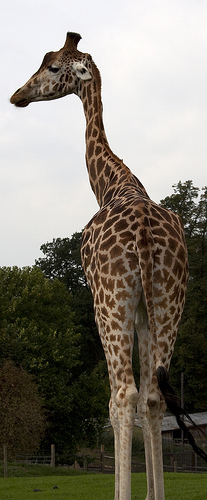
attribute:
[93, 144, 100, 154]
spot — brown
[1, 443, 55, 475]
poles — wooden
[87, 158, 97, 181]
spot — brown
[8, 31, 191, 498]
giraffe — tall, yellow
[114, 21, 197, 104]
sky — blue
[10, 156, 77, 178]
cloud — white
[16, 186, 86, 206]
cloud — white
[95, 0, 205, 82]
cloud — white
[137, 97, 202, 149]
cloud — white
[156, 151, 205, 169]
cloud — white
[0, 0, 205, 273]
sky — blue, clear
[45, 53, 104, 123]
giraffe — yellow, tall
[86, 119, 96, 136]
spot — brown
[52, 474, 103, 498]
grass — green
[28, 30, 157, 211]
giraffe — yellow, tall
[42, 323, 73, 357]
leaves — green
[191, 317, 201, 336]
leaves — green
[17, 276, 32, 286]
leaves — green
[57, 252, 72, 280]
leaves — green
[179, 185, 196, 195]
leaves — green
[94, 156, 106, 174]
spot — brown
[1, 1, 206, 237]
sky — blue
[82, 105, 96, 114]
spot — brown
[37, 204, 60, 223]
sky — blue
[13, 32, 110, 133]
giraffe — tall, yellow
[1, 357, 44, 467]
tree — smaller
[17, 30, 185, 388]
giraffe — tall, yellow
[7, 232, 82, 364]
tree — large, tall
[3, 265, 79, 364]
leaves — green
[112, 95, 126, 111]
clouds — white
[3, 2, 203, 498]
giraffe — yellow, tall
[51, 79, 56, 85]
spot — brown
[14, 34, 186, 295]
giraffe — tall, yellow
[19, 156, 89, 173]
cloud — white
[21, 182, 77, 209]
cloud — white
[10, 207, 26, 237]
cloud — white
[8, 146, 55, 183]
cloud — white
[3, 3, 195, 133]
sky — blue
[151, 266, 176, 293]
spot — brown